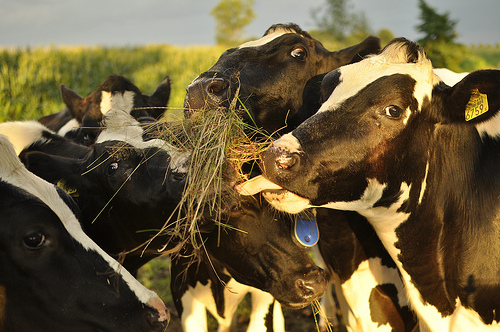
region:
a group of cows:
[8, 0, 496, 306]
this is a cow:
[263, 32, 496, 324]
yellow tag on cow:
[437, 50, 497, 155]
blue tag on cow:
[270, 170, 360, 287]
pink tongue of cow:
[214, 132, 309, 229]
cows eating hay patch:
[129, 75, 268, 245]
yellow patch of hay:
[128, 57, 283, 281]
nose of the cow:
[240, 93, 314, 208]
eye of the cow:
[373, 97, 420, 133]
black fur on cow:
[305, 87, 487, 306]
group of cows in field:
[3, 5, 498, 328]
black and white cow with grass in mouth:
[104, 23, 393, 280]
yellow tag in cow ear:
[461, 75, 494, 129]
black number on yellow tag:
[465, 93, 489, 123]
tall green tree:
[411, 0, 463, 46]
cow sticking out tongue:
[228, 42, 497, 328]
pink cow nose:
[138, 285, 172, 321]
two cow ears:
[48, 70, 174, 121]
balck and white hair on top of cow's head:
[353, 32, 428, 87]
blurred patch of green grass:
[0, 46, 212, 126]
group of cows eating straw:
[3, 7, 493, 328]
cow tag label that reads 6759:
[462, 76, 490, 129]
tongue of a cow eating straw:
[235, 165, 275, 202]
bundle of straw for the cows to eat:
[145, 90, 262, 263]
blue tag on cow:
[290, 213, 327, 252]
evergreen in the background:
[410, 0, 461, 47]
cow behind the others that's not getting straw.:
[35, 73, 178, 150]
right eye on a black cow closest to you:
[11, 213, 56, 259]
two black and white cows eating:
[176, 23, 498, 207]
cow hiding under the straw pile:
[177, 151, 387, 327]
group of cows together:
[15, 60, 464, 320]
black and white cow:
[309, 24, 498, 326]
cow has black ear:
[434, 63, 499, 143]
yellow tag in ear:
[455, 77, 490, 122]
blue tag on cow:
[277, 214, 329, 264]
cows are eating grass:
[132, 91, 299, 261]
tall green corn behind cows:
[23, 43, 172, 98]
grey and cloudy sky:
[67, 2, 170, 43]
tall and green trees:
[192, 11, 459, 36]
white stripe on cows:
[278, 61, 398, 150]